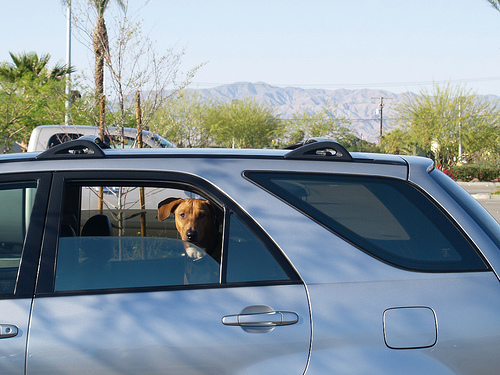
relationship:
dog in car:
[167, 192, 227, 260] [6, 105, 368, 318]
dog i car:
[167, 192, 227, 260] [6, 105, 368, 318]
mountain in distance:
[232, 46, 409, 142] [105, 16, 437, 174]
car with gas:
[6, 105, 368, 318] [366, 296, 450, 375]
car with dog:
[6, 105, 368, 318] [167, 192, 227, 260]